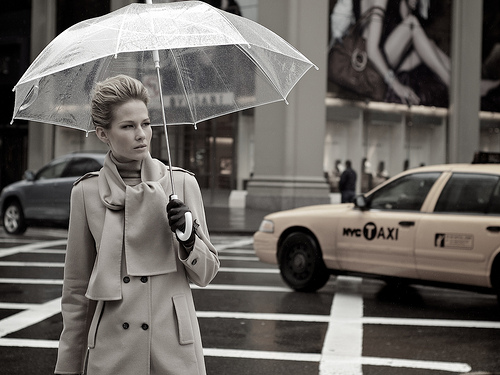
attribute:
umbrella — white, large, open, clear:
[9, 1, 323, 244]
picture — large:
[323, 0, 455, 117]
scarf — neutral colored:
[85, 151, 178, 301]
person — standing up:
[335, 155, 358, 202]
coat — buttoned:
[52, 154, 221, 373]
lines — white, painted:
[0, 238, 473, 373]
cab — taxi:
[249, 160, 484, 293]